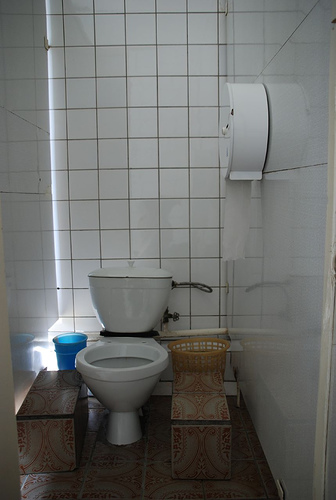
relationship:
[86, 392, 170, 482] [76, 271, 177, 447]
tile under toilet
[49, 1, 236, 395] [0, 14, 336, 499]
tile on wall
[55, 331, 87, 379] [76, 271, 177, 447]
bucket next to toilet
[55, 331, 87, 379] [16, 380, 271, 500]
bucket on floor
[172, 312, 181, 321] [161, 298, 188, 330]
knob on pipe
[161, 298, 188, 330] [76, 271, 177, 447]
pipe going to toilet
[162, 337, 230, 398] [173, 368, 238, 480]
basket on shelf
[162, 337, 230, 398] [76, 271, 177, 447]
basket next to toilet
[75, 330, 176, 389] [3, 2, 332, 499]
toilet seat in bathroom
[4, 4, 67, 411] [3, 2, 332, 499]
wall in bathroom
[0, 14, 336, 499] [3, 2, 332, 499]
wall in bathroom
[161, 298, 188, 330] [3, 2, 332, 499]
pipe in bathroom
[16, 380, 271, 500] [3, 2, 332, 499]
floor in bathroom